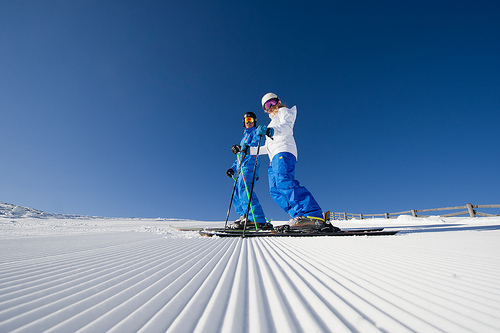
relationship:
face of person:
[243, 117, 255, 130] [227, 112, 270, 227]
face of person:
[261, 98, 278, 117] [229, 91, 329, 227]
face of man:
[241, 117, 255, 128] [225, 110, 263, 225]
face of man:
[260, 100, 278, 115] [240, 93, 328, 231]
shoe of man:
[285, 214, 327, 229] [226, 89, 336, 233]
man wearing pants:
[230, 90, 329, 229] [268, 151, 321, 218]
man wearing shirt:
[240, 93, 328, 231] [250, 103, 299, 157]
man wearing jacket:
[240, 93, 328, 231] [250, 102, 298, 162]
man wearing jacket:
[246, 92, 326, 223] [248, 105, 299, 164]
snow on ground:
[170, 241, 294, 316] [16, 248, 481, 329]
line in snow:
[261, 265, 287, 330] [20, 241, 480, 329]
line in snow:
[200, 271, 226, 330] [20, 241, 480, 329]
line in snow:
[168, 286, 199, 331] [20, 241, 480, 329]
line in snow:
[309, 301, 341, 331] [20, 241, 480, 329]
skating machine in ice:
[198, 222, 385, 235] [198, 237, 398, 263]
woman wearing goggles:
[243, 92, 335, 226] [264, 99, 279, 113]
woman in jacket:
[240, 93, 326, 232] [250, 102, 298, 162]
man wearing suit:
[222, 110, 267, 228] [229, 123, 269, 224]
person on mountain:
[240, 92, 326, 232] [0, 202, 172, 331]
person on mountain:
[225, 110, 265, 231] [0, 202, 172, 331]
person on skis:
[243, 88, 330, 227] [198, 229, 396, 238]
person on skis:
[227, 112, 270, 227] [177, 224, 381, 234]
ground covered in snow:
[37, 235, 465, 329] [213, 273, 335, 321]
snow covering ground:
[213, 273, 335, 321] [37, 235, 465, 329]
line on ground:
[176, 275, 207, 329] [1, 237, 318, 330]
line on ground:
[193, 276, 222, 330] [1, 237, 318, 330]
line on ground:
[267, 286, 290, 330] [1, 237, 318, 330]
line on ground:
[48, 286, 90, 331] [1, 237, 318, 330]